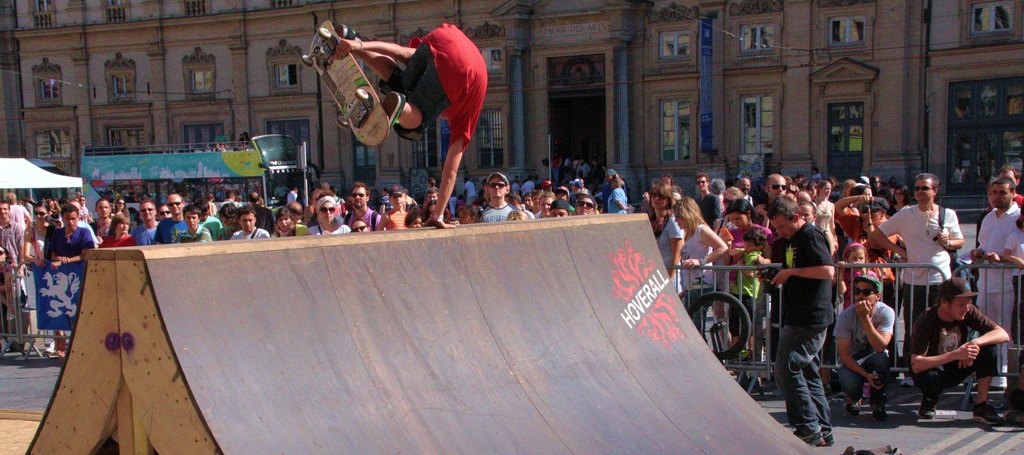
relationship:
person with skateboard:
[299, 20, 488, 230] [289, 9, 402, 154]